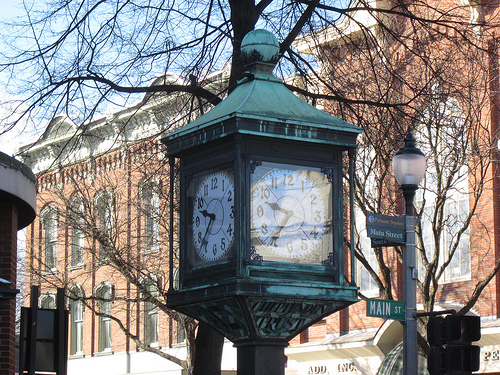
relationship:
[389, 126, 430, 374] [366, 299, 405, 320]
light post has a sign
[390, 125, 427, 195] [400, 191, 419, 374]
light on a pole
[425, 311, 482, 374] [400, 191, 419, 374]
walk light on pole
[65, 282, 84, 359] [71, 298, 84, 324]
window has pane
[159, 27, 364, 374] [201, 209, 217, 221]
clock has a hand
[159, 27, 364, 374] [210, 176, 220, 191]
clock has number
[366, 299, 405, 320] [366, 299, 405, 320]
sign says sign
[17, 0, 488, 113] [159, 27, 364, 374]
tree behind clock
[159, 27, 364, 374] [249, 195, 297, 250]
clock shows 9:35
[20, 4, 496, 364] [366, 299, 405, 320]
building behind sign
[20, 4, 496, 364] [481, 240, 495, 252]
building has bricks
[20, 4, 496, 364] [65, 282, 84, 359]
building has window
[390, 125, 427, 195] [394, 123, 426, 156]
light has a top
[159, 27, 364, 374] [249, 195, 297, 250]
clock says 9:35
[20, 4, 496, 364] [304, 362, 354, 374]
building says add. inc.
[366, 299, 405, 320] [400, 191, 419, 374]
sign on pole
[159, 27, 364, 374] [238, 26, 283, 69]
clock has a circle